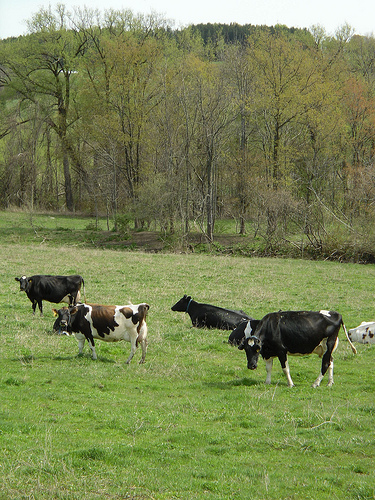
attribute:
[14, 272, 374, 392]
cows — grouped, various kinds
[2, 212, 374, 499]
field — green, brown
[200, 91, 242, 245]
tree — thin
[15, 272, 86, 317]
cow — standing, alert, black, white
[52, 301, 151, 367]
cow — standing, brown, white, black,brown,white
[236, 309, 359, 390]
cow — standing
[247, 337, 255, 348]
spot — white, heart shaped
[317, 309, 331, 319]
spot — white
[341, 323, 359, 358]
tail — white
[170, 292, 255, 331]
cow — black, laying down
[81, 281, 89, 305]
tail — white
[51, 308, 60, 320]
ear — brown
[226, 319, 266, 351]
cow — black, white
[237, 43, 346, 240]
tree — leafy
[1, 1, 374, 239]
trees — green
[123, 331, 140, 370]
leg — white